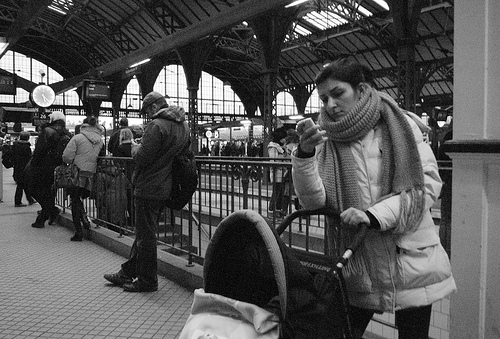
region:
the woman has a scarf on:
[280, 71, 449, 307]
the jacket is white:
[290, 146, 457, 308]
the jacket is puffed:
[290, 152, 461, 309]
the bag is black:
[166, 147, 216, 214]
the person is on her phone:
[105, 86, 200, 287]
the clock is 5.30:
[30, 82, 62, 112]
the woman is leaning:
[50, 124, 113, 235]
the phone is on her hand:
[278, 116, 331, 198]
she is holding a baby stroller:
[202, 69, 452, 331]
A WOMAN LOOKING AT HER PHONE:
[288, 53, 388, 181]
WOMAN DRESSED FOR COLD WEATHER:
[292, 48, 452, 305]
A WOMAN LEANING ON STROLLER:
[200, 66, 465, 328]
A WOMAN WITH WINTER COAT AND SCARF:
[274, 48, 464, 307]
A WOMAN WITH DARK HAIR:
[306, 51, 378, 111]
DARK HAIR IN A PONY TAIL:
[299, 48, 382, 95]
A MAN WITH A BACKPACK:
[116, 85, 187, 302]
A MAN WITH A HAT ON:
[134, 85, 171, 130]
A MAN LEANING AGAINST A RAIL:
[128, 83, 200, 284]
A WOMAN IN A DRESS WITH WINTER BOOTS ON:
[57, 109, 108, 247]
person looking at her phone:
[267, 58, 437, 253]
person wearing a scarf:
[306, 72, 416, 189]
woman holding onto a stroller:
[192, 42, 446, 333]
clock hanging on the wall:
[22, 67, 64, 129]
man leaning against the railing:
[108, 71, 252, 300]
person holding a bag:
[49, 96, 111, 248]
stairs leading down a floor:
[92, 149, 236, 286]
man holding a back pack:
[131, 93, 203, 220]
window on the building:
[8, 47, 109, 122]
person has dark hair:
[292, 32, 386, 105]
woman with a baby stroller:
[166, 57, 442, 337]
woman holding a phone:
[294, 115, 329, 150]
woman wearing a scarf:
[316, 83, 427, 273]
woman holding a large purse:
[51, 159, 81, 188]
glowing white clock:
[29, 82, 54, 109]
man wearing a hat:
[136, 90, 166, 115]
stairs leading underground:
[97, 207, 218, 275]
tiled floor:
[0, 204, 207, 336]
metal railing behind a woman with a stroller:
[26, 146, 458, 336]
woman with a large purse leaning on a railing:
[51, 113, 111, 251]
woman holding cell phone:
[291, 58, 454, 337]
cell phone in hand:
[290, 115, 330, 155]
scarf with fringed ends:
[315, 80, 424, 277]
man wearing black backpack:
[103, 92, 199, 293]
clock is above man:
[30, 84, 54, 107]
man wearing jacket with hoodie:
[129, 106, 188, 202]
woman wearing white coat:
[290, 108, 460, 311]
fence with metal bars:
[46, 155, 443, 274]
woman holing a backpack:
[2, 127, 42, 208]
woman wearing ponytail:
[55, 114, 104, 243]